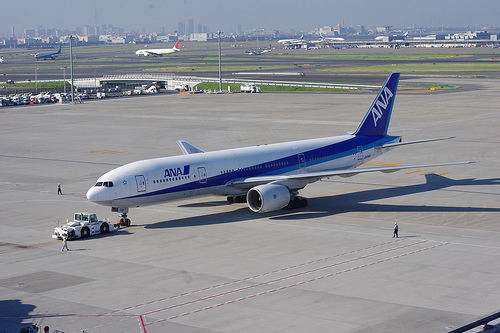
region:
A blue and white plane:
[89, 70, 465, 232]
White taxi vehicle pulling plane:
[54, 205, 121, 256]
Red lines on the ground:
[127, 228, 416, 332]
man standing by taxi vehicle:
[53, 230, 72, 255]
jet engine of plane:
[239, 176, 292, 224]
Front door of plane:
[130, 171, 157, 206]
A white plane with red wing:
[136, 31, 191, 71]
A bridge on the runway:
[64, 71, 213, 113]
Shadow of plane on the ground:
[140, 172, 497, 259]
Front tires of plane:
[120, 211, 132, 233]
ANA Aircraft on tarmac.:
[74, 70, 411, 215]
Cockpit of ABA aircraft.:
[88, 168, 126, 198]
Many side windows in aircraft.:
[215, 158, 317, 173]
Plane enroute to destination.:
[133, 40, 190, 59]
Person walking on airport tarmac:
[387, 218, 404, 240]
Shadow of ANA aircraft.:
[322, 166, 499, 220]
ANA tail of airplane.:
[362, 60, 403, 159]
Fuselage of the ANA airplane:
[122, 141, 362, 192]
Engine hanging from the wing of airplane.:
[244, 175, 305, 220]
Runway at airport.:
[242, 68, 360, 79]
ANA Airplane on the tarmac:
[79, 70, 456, 219]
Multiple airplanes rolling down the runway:
[19, 34, 190, 69]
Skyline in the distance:
[0, 16, 282, 43]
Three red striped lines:
[102, 227, 490, 332]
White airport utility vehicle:
[48, 205, 135, 242]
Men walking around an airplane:
[46, 71, 475, 274]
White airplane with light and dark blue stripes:
[73, 66, 467, 216]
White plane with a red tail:
[135, 33, 190, 63]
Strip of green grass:
[355, 62, 496, 72]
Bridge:
[79, 68, 206, 95]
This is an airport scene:
[20, 27, 482, 318]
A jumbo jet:
[81, 66, 481, 230]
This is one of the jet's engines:
[243, 175, 304, 222]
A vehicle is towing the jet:
[52, 176, 139, 251]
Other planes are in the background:
[24, 37, 190, 62]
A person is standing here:
[381, 218, 412, 245]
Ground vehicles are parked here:
[1, 92, 83, 105]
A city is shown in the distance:
[15, 16, 222, 46]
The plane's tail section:
[351, 70, 460, 162]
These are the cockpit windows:
[91, 174, 118, 194]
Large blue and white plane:
[73, 58, 441, 218]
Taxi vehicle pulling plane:
[48, 207, 125, 251]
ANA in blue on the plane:
[159, 166, 202, 181]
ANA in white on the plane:
[367, 84, 399, 140]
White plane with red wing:
[133, 35, 195, 69]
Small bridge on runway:
[78, 70, 207, 106]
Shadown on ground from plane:
[141, 170, 498, 269]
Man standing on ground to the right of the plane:
[384, 220, 410, 253]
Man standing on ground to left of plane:
[48, 178, 69, 196]